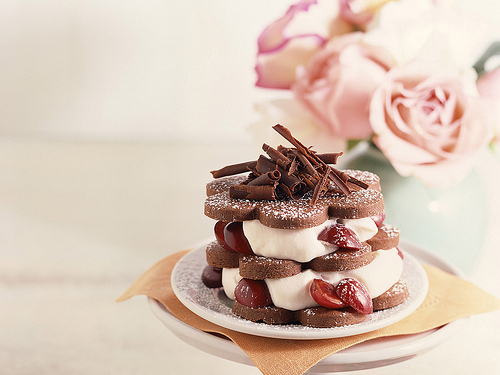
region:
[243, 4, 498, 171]
light pink and dark pink roses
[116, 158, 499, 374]
tan color napkin under plate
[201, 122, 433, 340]
shredded chocolate on top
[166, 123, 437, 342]
sliced strawberries on on cake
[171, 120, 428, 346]
whipped cream and strawberries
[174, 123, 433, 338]
whipped cream under chocolate cake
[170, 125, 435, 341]
chocolate cake shaped like flower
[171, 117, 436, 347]
three layer chocolate cake with whipped cream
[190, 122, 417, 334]
three layer chocolate cake with strawberries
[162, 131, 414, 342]
Desert on a plate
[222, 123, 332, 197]
shaved chocolate on plate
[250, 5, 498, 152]
roses on a plate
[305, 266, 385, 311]
fruit on a plate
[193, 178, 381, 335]
cake on a plate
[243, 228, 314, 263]
cream in the desert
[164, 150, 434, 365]
Desert on a plate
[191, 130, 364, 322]
Desert on a plate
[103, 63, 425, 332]
Desert on a plate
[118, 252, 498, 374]
tan cloth under plate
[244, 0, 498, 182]
flowers in the background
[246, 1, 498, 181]
pink flower arrangement in the back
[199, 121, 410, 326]
dessert on a white plate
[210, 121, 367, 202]
chocolate strips on top of dessert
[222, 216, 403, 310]
white marshmallows between chocolate layers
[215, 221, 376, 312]
red cherries between layers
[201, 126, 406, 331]
three layered chocolate dessert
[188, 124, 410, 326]
dessert covered in white sugar dusting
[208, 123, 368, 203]
chocolate on top of dessert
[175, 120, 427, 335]
a chocolate and cream dessert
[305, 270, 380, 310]
halved cherries in a dessert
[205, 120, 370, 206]
shavings of milk chocolate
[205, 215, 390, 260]
cherries and whipped cream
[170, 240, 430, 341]
a small dessert plate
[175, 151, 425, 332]
powered sugar finely dusted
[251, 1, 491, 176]
bouquet of light pink roses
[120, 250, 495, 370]
an orange napkin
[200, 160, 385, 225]
flower shaped chocolate cake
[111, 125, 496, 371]
a three tier chocolate cake dessert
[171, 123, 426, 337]
chocolate dessert on small plate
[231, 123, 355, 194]
chocolate swirls on top of dessert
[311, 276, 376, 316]
purple fruit in dessert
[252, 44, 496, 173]
pink roses on the table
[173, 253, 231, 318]
powdered sugar dusted on plate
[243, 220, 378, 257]
layer of white whipped cream in dessert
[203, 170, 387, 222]
chocolate flower shaped pastry on dessert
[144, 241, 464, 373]
two round white plates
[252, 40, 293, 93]
rose with darker pink edges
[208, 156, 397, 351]
these are cookies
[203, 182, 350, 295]
the cookes are creme filled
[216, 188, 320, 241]
the cookies are brown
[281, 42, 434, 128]
the roses are pink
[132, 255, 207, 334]
the napkins are orange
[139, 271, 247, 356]
the napkin is under the plate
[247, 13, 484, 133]
the roses are behind the dessert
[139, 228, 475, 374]
small plate holds dessert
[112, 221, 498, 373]
napkin on small plate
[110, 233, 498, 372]
napkin on plate is brown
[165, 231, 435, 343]
tiny plate on napkin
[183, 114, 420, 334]
dessert piled on plate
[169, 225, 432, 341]
tiny plate is white